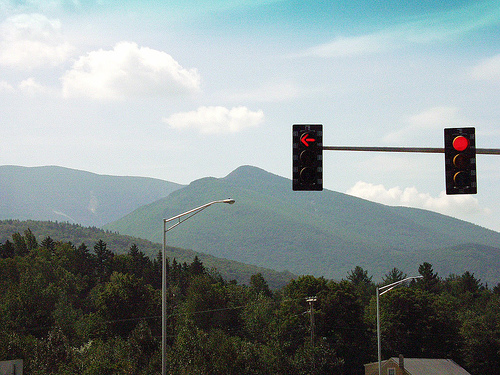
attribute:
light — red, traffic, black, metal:
[282, 110, 335, 190]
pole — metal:
[153, 194, 236, 281]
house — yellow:
[386, 348, 457, 370]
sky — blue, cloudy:
[198, 26, 269, 67]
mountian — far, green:
[53, 164, 103, 205]